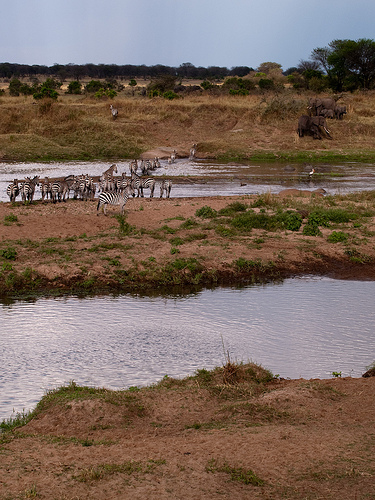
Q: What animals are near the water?
A: Zebras.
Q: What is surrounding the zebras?
A: Water.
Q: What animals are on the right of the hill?
A: Elephants.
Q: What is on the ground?
A: Water.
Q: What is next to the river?
A: Zebras.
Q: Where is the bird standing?
A: In the water.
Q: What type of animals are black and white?
A: Zebras.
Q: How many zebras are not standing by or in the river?
A: Two.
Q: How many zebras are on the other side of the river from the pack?
A: Three.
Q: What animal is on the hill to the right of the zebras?
A: Elephants.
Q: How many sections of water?
A: Two.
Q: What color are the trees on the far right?
A: Green.